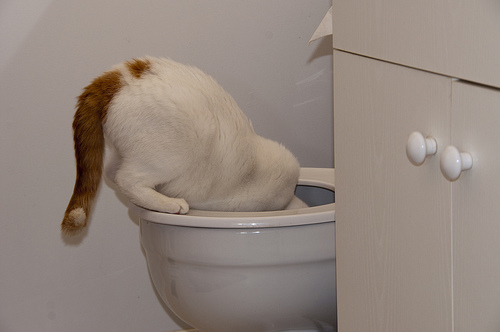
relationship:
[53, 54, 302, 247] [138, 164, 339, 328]
cat drinking out of toilet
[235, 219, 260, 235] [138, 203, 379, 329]
light reflection on toilet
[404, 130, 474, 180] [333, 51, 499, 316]
white nobs on cabinet doors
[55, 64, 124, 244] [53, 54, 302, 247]
tail of cat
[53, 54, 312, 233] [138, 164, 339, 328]
cat leaning into toilet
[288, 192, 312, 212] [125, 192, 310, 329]
cats head in toilet bowl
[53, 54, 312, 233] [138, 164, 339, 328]
cat in toilet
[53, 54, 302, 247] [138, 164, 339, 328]
cat in toilet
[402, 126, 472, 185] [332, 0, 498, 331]
handles on bathroom cabinet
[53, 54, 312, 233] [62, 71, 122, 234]
cat has tail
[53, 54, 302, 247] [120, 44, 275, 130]
cat has back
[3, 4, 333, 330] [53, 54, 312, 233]
wall behind cat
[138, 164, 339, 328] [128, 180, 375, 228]
toilet has seat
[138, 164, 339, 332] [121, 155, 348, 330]
toilet has bowl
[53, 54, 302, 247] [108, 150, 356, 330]
cat on toilet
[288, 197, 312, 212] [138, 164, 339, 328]
cats head in toilet